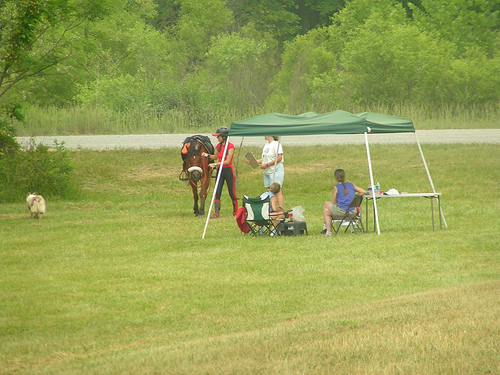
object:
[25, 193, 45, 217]
dog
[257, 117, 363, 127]
canopy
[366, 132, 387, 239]
pole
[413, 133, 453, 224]
pole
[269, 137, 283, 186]
pole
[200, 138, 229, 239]
pole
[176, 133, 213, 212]
horse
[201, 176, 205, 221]
leg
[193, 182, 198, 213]
leg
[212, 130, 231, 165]
female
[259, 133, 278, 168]
female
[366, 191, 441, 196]
table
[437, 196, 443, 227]
leg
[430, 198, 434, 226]
leg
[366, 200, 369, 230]
leg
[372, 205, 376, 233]
leg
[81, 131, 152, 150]
road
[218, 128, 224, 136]
helmet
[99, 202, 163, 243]
grass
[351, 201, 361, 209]
chair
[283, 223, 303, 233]
stool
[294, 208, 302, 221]
bag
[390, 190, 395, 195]
bag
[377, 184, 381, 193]
bottle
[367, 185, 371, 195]
bottle